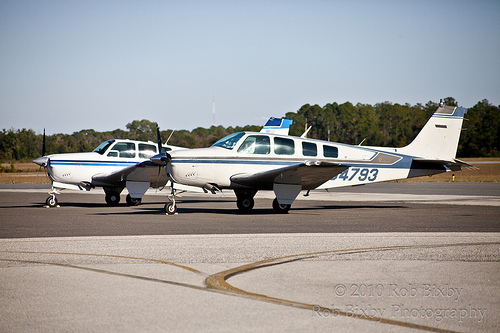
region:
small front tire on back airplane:
[39, 186, 70, 212]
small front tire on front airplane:
[168, 186, 192, 230]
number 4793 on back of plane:
[337, 154, 386, 194]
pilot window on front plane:
[243, 136, 271, 159]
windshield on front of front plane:
[216, 128, 239, 163]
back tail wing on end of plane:
[421, 96, 469, 193]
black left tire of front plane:
[264, 188, 300, 224]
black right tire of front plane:
[230, 192, 252, 217]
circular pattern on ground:
[211, 216, 498, 331]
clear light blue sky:
[261, 27, 476, 110]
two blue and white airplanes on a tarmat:
[20, 100, 482, 209]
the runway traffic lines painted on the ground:
[1, 238, 498, 331]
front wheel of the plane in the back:
[46, 194, 57, 208]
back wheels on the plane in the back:
[101, 188, 147, 205]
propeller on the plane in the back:
[37, 126, 49, 176]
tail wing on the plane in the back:
[262, 117, 294, 132]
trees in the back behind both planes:
[300, 108, 499, 159]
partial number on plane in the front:
[347, 168, 377, 180]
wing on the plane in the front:
[223, 160, 346, 190]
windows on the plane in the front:
[211, 132, 341, 157]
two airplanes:
[46, 129, 403, 221]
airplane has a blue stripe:
[211, 146, 397, 166]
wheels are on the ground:
[47, 177, 295, 224]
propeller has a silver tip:
[29, 141, 53, 182]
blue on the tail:
[261, 111, 295, 133]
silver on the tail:
[431, 99, 456, 117]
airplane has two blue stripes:
[63, 150, 104, 172]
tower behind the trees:
[204, 80, 234, 130]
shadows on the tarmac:
[155, 180, 312, 213]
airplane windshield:
[210, 126, 239, 147]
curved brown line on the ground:
[147, 251, 279, 304]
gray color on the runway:
[24, 210, 151, 224]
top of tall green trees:
[279, 88, 372, 115]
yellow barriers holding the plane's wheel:
[36, 200, 50, 211]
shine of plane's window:
[115, 139, 166, 158]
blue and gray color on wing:
[425, 93, 478, 131]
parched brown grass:
[7, 170, 35, 182]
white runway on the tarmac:
[388, 184, 465, 217]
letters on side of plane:
[327, 160, 390, 187]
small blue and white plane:
[116, 99, 472, 223]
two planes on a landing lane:
[25, 85, 479, 233]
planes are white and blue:
[25, 92, 480, 217]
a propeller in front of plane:
[140, 118, 187, 189]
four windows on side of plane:
[214, 125, 346, 160]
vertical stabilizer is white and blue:
[404, 95, 472, 162]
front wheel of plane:
[161, 192, 185, 217]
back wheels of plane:
[230, 191, 298, 219]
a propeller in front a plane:
[29, 124, 62, 184]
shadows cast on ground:
[8, 190, 408, 225]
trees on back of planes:
[6, 92, 496, 152]